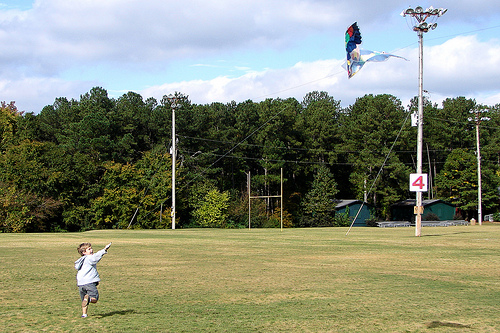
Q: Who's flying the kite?
A: The boy.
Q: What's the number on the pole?
A: 4.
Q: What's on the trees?
A: Green leaves.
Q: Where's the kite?
A: In the air.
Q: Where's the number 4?
A: On the pole.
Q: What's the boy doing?
A: Flying a kite.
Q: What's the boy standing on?
A: Green grass.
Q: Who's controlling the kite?
A: The boy.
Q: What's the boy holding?
A: Kite strings.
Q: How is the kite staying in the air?
A: Wind.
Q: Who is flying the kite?
A: Boy.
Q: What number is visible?
A: 4.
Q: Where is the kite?
A: Air.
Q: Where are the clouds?
A: Sky.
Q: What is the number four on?
A: Sign.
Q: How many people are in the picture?
A: One.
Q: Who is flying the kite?
A: Boy.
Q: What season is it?
A: Summer.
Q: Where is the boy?
A: Park.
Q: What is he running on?
A: Grass.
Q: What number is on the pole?
A: Four.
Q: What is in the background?
A: Trees.